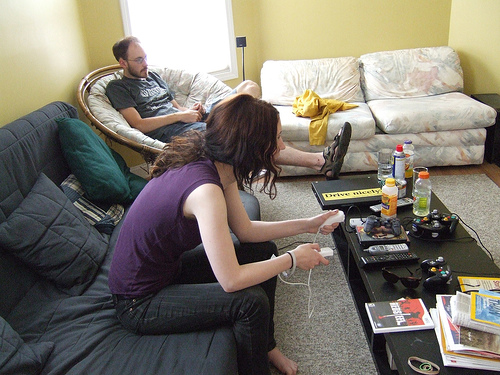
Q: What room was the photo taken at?
A: It was taken at the living room.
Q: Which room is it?
A: It is a living room.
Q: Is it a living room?
A: Yes, it is a living room.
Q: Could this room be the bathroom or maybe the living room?
A: It is the living room.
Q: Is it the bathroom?
A: No, it is the living room.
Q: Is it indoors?
A: Yes, it is indoors.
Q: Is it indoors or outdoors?
A: It is indoors.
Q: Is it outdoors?
A: No, it is indoors.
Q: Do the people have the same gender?
A: No, they are both male and female.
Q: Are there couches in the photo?
A: Yes, there is a couch.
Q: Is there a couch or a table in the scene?
A: Yes, there is a couch.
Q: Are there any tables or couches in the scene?
A: Yes, there is a couch.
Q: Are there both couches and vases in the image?
A: No, there is a couch but no vases.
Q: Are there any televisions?
A: No, there are no televisions.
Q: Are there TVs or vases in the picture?
A: No, there are no TVs or vases.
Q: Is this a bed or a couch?
A: This is a couch.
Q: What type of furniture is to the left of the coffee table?
A: The piece of furniture is a couch.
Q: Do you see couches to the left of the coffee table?
A: Yes, there is a couch to the left of the coffee table.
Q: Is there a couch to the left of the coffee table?
A: Yes, there is a couch to the left of the coffee table.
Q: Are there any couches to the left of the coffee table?
A: Yes, there is a couch to the left of the coffee table.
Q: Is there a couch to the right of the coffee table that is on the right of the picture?
A: No, the couch is to the left of the coffee table.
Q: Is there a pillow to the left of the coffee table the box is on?
A: No, there is a couch to the left of the coffee table.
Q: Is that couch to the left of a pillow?
A: No, the couch is to the left of the coffee table.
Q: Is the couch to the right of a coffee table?
A: No, the couch is to the left of a coffee table.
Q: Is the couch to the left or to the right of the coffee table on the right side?
A: The couch is to the left of the coffee table.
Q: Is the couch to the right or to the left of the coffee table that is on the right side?
A: The couch is to the left of the coffee table.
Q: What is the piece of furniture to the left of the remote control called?
A: The piece of furniture is a couch.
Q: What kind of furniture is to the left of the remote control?
A: The piece of furniture is a couch.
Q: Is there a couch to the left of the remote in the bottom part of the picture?
A: Yes, there is a couch to the left of the remote.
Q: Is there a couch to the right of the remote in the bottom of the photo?
A: No, the couch is to the left of the remote.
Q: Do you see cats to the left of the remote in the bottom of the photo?
A: No, there is a couch to the left of the remote.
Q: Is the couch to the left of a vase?
A: No, the couch is to the left of a remote control.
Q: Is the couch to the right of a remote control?
A: No, the couch is to the left of a remote control.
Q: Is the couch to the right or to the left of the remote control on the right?
A: The couch is to the left of the remote.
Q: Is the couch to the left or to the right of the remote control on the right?
A: The couch is to the left of the remote.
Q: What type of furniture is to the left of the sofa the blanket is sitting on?
A: The piece of furniture is a couch.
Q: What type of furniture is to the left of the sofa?
A: The piece of furniture is a couch.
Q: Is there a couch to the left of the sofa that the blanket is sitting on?
A: Yes, there is a couch to the left of the sofa.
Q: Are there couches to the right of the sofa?
A: No, the couch is to the left of the sofa.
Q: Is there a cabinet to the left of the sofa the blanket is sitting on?
A: No, there is a couch to the left of the sofa.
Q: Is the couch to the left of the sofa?
A: Yes, the couch is to the left of the sofa.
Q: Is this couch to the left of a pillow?
A: No, the couch is to the left of the sofa.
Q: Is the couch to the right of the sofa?
A: No, the couch is to the left of the sofa.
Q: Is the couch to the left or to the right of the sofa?
A: The couch is to the left of the sofa.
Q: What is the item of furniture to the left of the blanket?
A: The piece of furniture is a couch.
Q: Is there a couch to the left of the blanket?
A: Yes, there is a couch to the left of the blanket.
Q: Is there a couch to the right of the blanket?
A: No, the couch is to the left of the blanket.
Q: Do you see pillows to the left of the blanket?
A: No, there is a couch to the left of the blanket.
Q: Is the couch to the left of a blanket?
A: Yes, the couch is to the left of a blanket.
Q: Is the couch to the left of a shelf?
A: No, the couch is to the left of a blanket.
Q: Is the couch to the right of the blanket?
A: No, the couch is to the left of the blanket.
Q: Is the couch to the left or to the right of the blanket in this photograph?
A: The couch is to the left of the blanket.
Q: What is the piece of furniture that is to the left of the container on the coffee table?
A: The piece of furniture is a couch.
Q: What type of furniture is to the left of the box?
A: The piece of furniture is a couch.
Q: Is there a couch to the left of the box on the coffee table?
A: Yes, there is a couch to the left of the box.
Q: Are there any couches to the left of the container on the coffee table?
A: Yes, there is a couch to the left of the box.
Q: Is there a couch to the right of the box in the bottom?
A: No, the couch is to the left of the box.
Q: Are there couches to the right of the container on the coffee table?
A: No, the couch is to the left of the box.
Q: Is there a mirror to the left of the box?
A: No, there is a couch to the left of the box.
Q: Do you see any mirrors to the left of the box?
A: No, there is a couch to the left of the box.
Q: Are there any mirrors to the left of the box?
A: No, there is a couch to the left of the box.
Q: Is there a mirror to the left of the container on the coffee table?
A: No, there is a couch to the left of the box.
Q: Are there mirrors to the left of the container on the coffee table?
A: No, there is a couch to the left of the box.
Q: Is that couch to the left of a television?
A: No, the couch is to the left of a box.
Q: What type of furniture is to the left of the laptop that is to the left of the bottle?
A: The piece of furniture is a couch.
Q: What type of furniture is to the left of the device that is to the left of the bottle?
A: The piece of furniture is a couch.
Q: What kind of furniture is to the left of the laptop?
A: The piece of furniture is a couch.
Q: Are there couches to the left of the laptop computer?
A: Yes, there is a couch to the left of the laptop computer.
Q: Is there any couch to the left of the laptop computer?
A: Yes, there is a couch to the left of the laptop computer.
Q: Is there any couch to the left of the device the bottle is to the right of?
A: Yes, there is a couch to the left of the laptop computer.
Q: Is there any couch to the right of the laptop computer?
A: No, the couch is to the left of the laptop computer.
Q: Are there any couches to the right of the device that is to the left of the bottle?
A: No, the couch is to the left of the laptop computer.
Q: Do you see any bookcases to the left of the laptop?
A: No, there is a couch to the left of the laptop.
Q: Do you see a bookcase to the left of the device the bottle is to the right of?
A: No, there is a couch to the left of the laptop.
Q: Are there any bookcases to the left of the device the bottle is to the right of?
A: No, there is a couch to the left of the laptop.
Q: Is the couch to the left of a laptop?
A: Yes, the couch is to the left of a laptop.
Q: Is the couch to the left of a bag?
A: No, the couch is to the left of a laptop.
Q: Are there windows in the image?
A: Yes, there is a window.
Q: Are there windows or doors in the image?
A: Yes, there is a window.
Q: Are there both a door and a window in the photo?
A: No, there is a window but no doors.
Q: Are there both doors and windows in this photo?
A: No, there is a window but no doors.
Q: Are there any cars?
A: No, there are no cars.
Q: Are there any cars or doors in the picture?
A: No, there are no cars or doors.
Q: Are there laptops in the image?
A: Yes, there is a laptop.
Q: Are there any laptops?
A: Yes, there is a laptop.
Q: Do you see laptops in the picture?
A: Yes, there is a laptop.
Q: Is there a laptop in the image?
A: Yes, there is a laptop.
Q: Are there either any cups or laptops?
A: Yes, there is a laptop.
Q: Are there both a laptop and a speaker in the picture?
A: No, there is a laptop but no speakers.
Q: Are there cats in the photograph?
A: No, there are no cats.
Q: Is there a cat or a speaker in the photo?
A: No, there are no cats or speakers.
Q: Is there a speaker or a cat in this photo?
A: No, there are no cats or speakers.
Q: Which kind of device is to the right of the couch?
A: The device is a laptop.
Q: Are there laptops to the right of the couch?
A: Yes, there is a laptop to the right of the couch.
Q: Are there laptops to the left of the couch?
A: No, the laptop is to the right of the couch.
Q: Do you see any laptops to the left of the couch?
A: No, the laptop is to the right of the couch.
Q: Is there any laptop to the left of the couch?
A: No, the laptop is to the right of the couch.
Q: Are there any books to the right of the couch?
A: No, there is a laptop to the right of the couch.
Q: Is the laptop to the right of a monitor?
A: No, the laptop is to the right of the couch.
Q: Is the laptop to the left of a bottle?
A: Yes, the laptop is to the left of a bottle.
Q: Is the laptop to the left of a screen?
A: No, the laptop is to the left of a bottle.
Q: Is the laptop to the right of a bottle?
A: No, the laptop is to the left of a bottle.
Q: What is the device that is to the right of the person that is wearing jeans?
A: The device is a laptop.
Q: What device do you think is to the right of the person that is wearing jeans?
A: The device is a laptop.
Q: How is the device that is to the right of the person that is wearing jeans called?
A: The device is a laptop.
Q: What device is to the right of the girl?
A: The device is a laptop.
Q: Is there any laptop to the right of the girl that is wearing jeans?
A: Yes, there is a laptop to the right of the girl.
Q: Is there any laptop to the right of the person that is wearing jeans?
A: Yes, there is a laptop to the right of the girl.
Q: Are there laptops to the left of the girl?
A: No, the laptop is to the right of the girl.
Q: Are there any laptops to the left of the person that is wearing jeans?
A: No, the laptop is to the right of the girl.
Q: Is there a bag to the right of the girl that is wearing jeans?
A: No, there is a laptop to the right of the girl.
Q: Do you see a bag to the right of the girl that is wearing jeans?
A: No, there is a laptop to the right of the girl.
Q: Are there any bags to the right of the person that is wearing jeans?
A: No, there is a laptop to the right of the girl.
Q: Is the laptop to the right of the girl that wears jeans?
A: Yes, the laptop is to the right of the girl.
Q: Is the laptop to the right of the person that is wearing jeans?
A: Yes, the laptop is to the right of the girl.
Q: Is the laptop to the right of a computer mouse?
A: No, the laptop is to the right of the girl.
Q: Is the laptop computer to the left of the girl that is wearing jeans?
A: No, the laptop computer is to the right of the girl.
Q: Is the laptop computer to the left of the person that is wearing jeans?
A: No, the laptop computer is to the right of the girl.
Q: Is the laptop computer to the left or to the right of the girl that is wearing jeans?
A: The laptop computer is to the right of the girl.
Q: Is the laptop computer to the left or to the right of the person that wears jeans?
A: The laptop computer is to the right of the girl.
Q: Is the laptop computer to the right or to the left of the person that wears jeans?
A: The laptop computer is to the right of the girl.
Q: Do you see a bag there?
A: No, there are no bags.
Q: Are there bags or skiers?
A: No, there are no bags or skiers.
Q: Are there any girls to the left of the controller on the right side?
A: Yes, there is a girl to the left of the controller.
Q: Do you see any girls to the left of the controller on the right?
A: Yes, there is a girl to the left of the controller.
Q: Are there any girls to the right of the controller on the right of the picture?
A: No, the girl is to the left of the controller.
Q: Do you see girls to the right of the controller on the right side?
A: No, the girl is to the left of the controller.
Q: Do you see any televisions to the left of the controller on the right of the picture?
A: No, there is a girl to the left of the controller.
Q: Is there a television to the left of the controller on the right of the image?
A: No, there is a girl to the left of the controller.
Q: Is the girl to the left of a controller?
A: Yes, the girl is to the left of a controller.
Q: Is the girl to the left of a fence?
A: No, the girl is to the left of a controller.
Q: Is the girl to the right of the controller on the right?
A: No, the girl is to the left of the controller.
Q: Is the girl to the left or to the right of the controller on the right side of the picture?
A: The girl is to the left of the controller.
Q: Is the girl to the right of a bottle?
A: No, the girl is to the left of a bottle.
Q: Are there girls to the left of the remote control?
A: Yes, there is a girl to the left of the remote control.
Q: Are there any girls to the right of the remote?
A: No, the girl is to the left of the remote.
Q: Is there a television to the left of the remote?
A: No, there is a girl to the left of the remote.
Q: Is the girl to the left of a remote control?
A: Yes, the girl is to the left of a remote control.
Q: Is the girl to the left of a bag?
A: No, the girl is to the left of a remote control.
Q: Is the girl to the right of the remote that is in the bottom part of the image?
A: No, the girl is to the left of the remote.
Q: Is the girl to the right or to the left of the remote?
A: The girl is to the left of the remote.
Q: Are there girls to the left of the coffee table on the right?
A: Yes, there is a girl to the left of the coffee table.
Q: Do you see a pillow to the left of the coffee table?
A: No, there is a girl to the left of the coffee table.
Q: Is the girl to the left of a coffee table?
A: Yes, the girl is to the left of a coffee table.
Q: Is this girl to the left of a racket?
A: No, the girl is to the left of a coffee table.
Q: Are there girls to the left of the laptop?
A: Yes, there is a girl to the left of the laptop.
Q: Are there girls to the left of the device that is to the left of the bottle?
A: Yes, there is a girl to the left of the laptop.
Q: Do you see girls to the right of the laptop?
A: No, the girl is to the left of the laptop.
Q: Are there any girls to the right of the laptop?
A: No, the girl is to the left of the laptop.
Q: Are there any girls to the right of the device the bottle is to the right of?
A: No, the girl is to the left of the laptop.